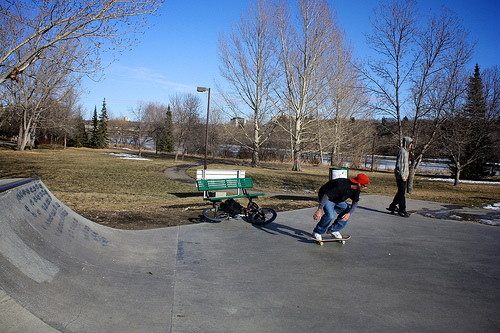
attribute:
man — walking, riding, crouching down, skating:
[315, 174, 369, 240]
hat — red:
[349, 174, 372, 183]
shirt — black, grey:
[320, 181, 367, 207]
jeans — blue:
[318, 202, 360, 234]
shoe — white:
[313, 231, 348, 242]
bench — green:
[198, 180, 267, 197]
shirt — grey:
[316, 199, 359, 215]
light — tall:
[195, 85, 213, 97]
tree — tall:
[0, 4, 498, 192]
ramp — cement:
[3, 179, 499, 323]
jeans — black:
[394, 175, 410, 214]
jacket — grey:
[315, 198, 362, 222]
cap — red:
[348, 171, 368, 191]